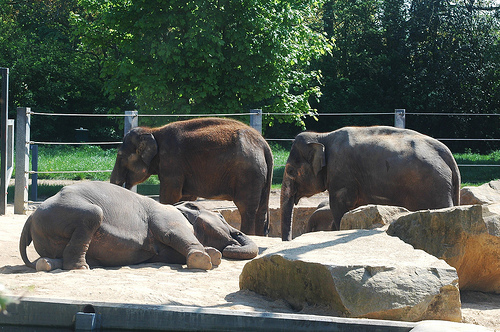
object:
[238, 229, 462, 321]
rock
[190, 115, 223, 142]
hair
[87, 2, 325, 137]
tree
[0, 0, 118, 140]
tree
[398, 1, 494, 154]
tree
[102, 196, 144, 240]
grey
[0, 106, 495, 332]
ground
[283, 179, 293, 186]
stain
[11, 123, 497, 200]
grass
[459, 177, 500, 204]
rock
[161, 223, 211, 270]
leg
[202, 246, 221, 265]
leg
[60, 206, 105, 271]
leg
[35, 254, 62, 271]
leg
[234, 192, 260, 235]
leg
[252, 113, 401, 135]
wall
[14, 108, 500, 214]
fence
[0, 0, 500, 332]
zoo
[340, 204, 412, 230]
rock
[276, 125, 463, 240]
animal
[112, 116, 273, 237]
animal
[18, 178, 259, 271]
animal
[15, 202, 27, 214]
brick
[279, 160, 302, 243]
trunk